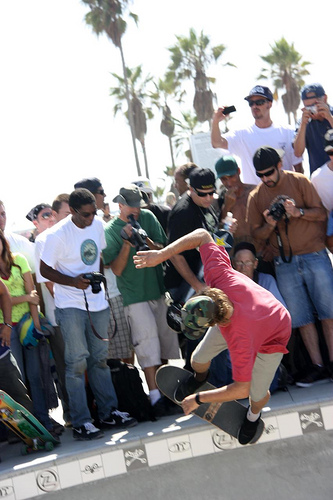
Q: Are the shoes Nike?
A: Yes, the shoes are nike.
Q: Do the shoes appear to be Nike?
A: Yes, the shoes are nike.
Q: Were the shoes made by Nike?
A: Yes, the shoes were made by nike.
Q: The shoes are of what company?
A: The shoes are nike.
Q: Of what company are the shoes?
A: The shoes are nike.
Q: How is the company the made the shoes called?
A: The company is nike.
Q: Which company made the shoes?
A: Nike made nike.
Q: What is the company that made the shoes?
A: The company that made the shoes is nike.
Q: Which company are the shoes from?
A: The shoes are from nike.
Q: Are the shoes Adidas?
A: No, the shoes are nike.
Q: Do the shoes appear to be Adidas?
A: No, the shoes are nike.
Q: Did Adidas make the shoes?
A: No, the shoes were made by nike.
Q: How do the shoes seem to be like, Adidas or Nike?
A: The shoes are nike.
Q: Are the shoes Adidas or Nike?
A: The shoes are nike.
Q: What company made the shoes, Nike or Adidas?
A: The shoes were made nike.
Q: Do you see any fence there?
A: No, there are no fences.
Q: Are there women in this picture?
A: Yes, there is a woman.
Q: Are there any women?
A: Yes, there is a woman.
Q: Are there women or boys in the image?
A: Yes, there is a woman.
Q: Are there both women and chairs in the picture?
A: No, there is a woman but no chairs.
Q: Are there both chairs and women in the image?
A: No, there is a woman but no chairs.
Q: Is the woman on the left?
A: Yes, the woman is on the left of the image.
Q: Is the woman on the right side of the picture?
A: No, the woman is on the left of the image.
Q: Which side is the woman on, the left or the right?
A: The woman is on the left of the image.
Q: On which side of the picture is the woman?
A: The woman is on the left of the image.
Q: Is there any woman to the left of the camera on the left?
A: Yes, there is a woman to the left of the camera.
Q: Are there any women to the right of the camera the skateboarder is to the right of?
A: No, the woman is to the left of the camera.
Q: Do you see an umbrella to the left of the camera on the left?
A: No, there is a woman to the left of the camera.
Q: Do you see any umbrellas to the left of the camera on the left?
A: No, there is a woman to the left of the camera.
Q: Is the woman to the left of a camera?
A: Yes, the woman is to the left of a camera.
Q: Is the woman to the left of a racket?
A: No, the woman is to the left of a camera.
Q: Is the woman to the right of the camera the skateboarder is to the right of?
A: No, the woman is to the left of the camera.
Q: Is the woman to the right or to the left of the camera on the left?
A: The woman is to the left of the camera.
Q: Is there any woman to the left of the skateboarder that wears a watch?
A: Yes, there is a woman to the left of the skateboarder.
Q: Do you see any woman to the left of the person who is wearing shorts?
A: Yes, there is a woman to the left of the skateboarder.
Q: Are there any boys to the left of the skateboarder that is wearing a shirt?
A: No, there is a woman to the left of the skateboarder.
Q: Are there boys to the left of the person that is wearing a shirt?
A: No, there is a woman to the left of the skateboarder.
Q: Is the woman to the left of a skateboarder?
A: Yes, the woman is to the left of a skateboarder.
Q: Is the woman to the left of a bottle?
A: No, the woman is to the left of a skateboarder.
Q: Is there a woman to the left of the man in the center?
A: Yes, there is a woman to the left of the man.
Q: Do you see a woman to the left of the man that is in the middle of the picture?
A: Yes, there is a woman to the left of the man.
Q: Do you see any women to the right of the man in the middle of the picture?
A: No, the woman is to the left of the man.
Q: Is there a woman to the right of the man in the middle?
A: No, the woman is to the left of the man.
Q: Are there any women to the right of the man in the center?
A: No, the woman is to the left of the man.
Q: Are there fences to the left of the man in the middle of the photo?
A: No, there is a woman to the left of the man.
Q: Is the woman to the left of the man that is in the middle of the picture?
A: Yes, the woman is to the left of the man.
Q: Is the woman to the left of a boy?
A: No, the woman is to the left of the man.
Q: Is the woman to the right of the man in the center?
A: No, the woman is to the left of the man.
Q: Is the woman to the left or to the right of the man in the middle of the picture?
A: The woman is to the left of the man.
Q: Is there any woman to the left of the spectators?
A: Yes, there is a woman to the left of the spectators.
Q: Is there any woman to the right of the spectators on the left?
A: No, the woman is to the left of the spectators.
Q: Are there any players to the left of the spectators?
A: No, there is a woman to the left of the spectators.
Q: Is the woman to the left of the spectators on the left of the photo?
A: Yes, the woman is to the left of the spectators.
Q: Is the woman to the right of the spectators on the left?
A: No, the woman is to the left of the spectators.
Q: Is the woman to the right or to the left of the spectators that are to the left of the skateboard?
A: The woman is to the left of the spectators.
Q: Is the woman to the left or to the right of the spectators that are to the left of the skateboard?
A: The woman is to the left of the spectators.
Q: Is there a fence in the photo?
A: No, there are no fences.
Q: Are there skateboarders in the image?
A: Yes, there is a skateboarder.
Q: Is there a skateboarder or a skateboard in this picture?
A: Yes, there is a skateboarder.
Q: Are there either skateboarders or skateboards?
A: Yes, there is a skateboarder.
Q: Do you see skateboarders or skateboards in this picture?
A: Yes, there is a skateboarder.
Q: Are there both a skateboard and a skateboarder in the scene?
A: Yes, there are both a skateboarder and a skateboard.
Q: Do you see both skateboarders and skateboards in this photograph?
A: Yes, there are both a skateboarder and a skateboard.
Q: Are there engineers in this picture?
A: No, there are no engineers.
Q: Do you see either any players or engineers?
A: No, there are no engineers or players.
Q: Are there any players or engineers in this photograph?
A: No, there are no engineers or players.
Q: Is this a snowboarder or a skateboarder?
A: This is a skateboarder.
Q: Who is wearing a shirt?
A: The skateboarder is wearing a shirt.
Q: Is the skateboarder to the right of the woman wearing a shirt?
A: Yes, the skateboarder is wearing a shirt.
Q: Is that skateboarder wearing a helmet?
A: No, the skateboarder is wearing a shirt.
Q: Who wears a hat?
A: The skateboarder wears a hat.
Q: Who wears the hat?
A: The skateboarder wears a hat.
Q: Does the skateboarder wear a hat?
A: Yes, the skateboarder wears a hat.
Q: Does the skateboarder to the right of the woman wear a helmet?
A: No, the skateboarder wears a hat.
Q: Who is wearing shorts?
A: The skateboarder is wearing shorts.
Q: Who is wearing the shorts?
A: The skateboarder is wearing shorts.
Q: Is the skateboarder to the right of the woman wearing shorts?
A: Yes, the skateboarder is wearing shorts.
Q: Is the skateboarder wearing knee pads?
A: No, the skateboarder is wearing shorts.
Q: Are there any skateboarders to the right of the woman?
A: Yes, there is a skateboarder to the right of the woman.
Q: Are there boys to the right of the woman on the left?
A: No, there is a skateboarder to the right of the woman.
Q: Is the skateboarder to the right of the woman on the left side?
A: Yes, the skateboarder is to the right of the woman.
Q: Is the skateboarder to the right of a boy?
A: No, the skateboarder is to the right of the woman.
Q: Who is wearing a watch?
A: The skateboarder is wearing a watch.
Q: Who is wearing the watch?
A: The skateboarder is wearing a watch.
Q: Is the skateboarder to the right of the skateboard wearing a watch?
A: Yes, the skateboarder is wearing a watch.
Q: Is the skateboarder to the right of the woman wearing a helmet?
A: No, the skateboarder is wearing a watch.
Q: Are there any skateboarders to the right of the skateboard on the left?
A: Yes, there is a skateboarder to the right of the skateboard.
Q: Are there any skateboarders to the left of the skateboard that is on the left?
A: No, the skateboarder is to the right of the skateboard.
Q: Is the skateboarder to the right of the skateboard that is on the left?
A: Yes, the skateboarder is to the right of the skateboard.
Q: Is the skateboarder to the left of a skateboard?
A: No, the skateboarder is to the right of a skateboard.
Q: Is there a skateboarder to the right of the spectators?
A: Yes, there is a skateboarder to the right of the spectators.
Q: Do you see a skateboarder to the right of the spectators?
A: Yes, there is a skateboarder to the right of the spectators.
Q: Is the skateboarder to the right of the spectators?
A: Yes, the skateboarder is to the right of the spectators.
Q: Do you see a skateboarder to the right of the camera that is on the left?
A: Yes, there is a skateboarder to the right of the camera.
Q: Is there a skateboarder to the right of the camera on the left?
A: Yes, there is a skateboarder to the right of the camera.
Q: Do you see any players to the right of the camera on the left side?
A: No, there is a skateboarder to the right of the camera.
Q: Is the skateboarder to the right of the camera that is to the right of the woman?
A: Yes, the skateboarder is to the right of the camera.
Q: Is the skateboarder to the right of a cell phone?
A: No, the skateboarder is to the right of the camera.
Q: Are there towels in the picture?
A: No, there are no towels.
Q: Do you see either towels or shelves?
A: No, there are no towels or shelves.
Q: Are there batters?
A: No, there are no batters.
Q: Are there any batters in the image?
A: No, there are no batters.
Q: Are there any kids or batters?
A: No, there are no batters or kids.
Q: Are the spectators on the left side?
A: Yes, the spectators are on the left of the image.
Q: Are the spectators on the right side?
A: No, the spectators are on the left of the image.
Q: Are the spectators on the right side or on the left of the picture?
A: The spectators are on the left of the image.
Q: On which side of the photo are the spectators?
A: The spectators are on the left of the image.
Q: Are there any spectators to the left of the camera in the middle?
A: Yes, there are spectators to the left of the camera.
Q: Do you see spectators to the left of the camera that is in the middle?
A: Yes, there are spectators to the left of the camera.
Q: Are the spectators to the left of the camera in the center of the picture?
A: Yes, the spectators are to the left of the camera.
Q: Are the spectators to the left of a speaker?
A: No, the spectators are to the left of the camera.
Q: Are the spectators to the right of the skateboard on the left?
A: Yes, the spectators are to the right of the skateboard.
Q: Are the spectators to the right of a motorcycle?
A: No, the spectators are to the right of the skateboard.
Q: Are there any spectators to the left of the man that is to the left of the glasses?
A: Yes, there are spectators to the left of the man.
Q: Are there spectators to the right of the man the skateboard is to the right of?
A: No, the spectators are to the left of the man.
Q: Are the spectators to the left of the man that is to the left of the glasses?
A: Yes, the spectators are to the left of the man.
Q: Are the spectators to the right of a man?
A: No, the spectators are to the left of a man.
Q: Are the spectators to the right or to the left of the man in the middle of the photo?
A: The spectators are to the left of the man.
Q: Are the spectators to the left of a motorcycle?
A: No, the spectators are to the left of the skateboard.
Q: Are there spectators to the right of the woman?
A: Yes, there are spectators to the right of the woman.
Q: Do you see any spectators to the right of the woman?
A: Yes, there are spectators to the right of the woman.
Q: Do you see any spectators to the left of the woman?
A: No, the spectators are to the right of the woman.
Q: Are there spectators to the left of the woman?
A: No, the spectators are to the right of the woman.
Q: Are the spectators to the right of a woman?
A: Yes, the spectators are to the right of a woman.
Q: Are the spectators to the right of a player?
A: No, the spectators are to the right of a woman.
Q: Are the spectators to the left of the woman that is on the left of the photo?
A: No, the spectators are to the right of the woman.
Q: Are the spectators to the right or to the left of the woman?
A: The spectators are to the right of the woman.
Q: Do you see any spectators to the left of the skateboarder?
A: Yes, there are spectators to the left of the skateboarder.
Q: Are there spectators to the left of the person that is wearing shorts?
A: Yes, there are spectators to the left of the skateboarder.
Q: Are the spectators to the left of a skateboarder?
A: Yes, the spectators are to the left of a skateboarder.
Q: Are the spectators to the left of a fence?
A: No, the spectators are to the left of a skateboarder.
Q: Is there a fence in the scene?
A: No, there are no fences.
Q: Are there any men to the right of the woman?
A: Yes, there is a man to the right of the woman.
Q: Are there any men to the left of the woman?
A: No, the man is to the right of the woman.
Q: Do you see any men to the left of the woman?
A: No, the man is to the right of the woman.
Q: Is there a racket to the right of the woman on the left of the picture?
A: No, there is a man to the right of the woman.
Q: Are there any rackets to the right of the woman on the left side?
A: No, there is a man to the right of the woman.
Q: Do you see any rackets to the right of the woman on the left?
A: No, there is a man to the right of the woman.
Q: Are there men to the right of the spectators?
A: Yes, there is a man to the right of the spectators.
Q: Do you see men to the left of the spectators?
A: No, the man is to the right of the spectators.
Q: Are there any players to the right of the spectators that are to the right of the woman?
A: No, there is a man to the right of the spectators.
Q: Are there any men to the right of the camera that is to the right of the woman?
A: Yes, there is a man to the right of the camera.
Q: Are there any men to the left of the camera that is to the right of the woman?
A: No, the man is to the right of the camera.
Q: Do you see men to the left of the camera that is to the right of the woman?
A: No, the man is to the right of the camera.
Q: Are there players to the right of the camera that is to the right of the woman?
A: No, there is a man to the right of the camera.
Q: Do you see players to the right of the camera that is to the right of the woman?
A: No, there is a man to the right of the camera.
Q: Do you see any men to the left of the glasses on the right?
A: Yes, there is a man to the left of the glasses.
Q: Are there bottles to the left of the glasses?
A: No, there is a man to the left of the glasses.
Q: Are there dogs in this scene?
A: No, there are no dogs.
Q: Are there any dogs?
A: No, there are no dogs.